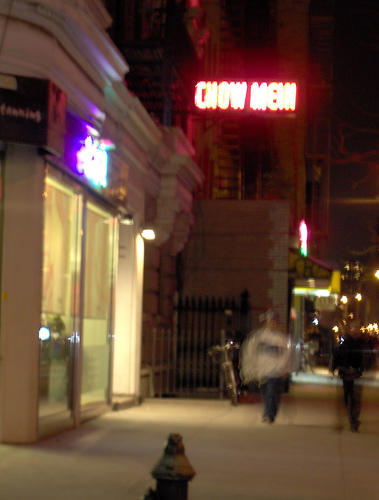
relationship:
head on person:
[256, 307, 286, 327] [236, 304, 304, 426]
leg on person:
[260, 376, 284, 426] [239, 306, 294, 427]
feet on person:
[259, 413, 276, 422] [239, 306, 294, 427]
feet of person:
[347, 415, 361, 435] [318, 320, 374, 435]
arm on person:
[244, 330, 267, 353] [241, 308, 314, 428]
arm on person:
[234, 335, 254, 390] [233, 301, 301, 430]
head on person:
[330, 322, 364, 351] [298, 307, 359, 408]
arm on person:
[327, 342, 339, 377] [328, 324, 374, 431]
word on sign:
[188, 80, 245, 114] [194, 78, 294, 112]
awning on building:
[290, 245, 338, 279] [171, 47, 310, 398]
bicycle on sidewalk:
[207, 340, 240, 406] [216, 330, 247, 401]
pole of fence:
[158, 330, 165, 398] [147, 325, 231, 395]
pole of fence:
[163, 325, 172, 395] [175, 286, 250, 392]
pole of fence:
[170, 326, 179, 395] [147, 325, 231, 395]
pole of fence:
[176, 328, 185, 399] [175, 286, 250, 392]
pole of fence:
[184, 328, 190, 397] [147, 325, 231, 395]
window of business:
[42, 178, 114, 422] [0, 0, 195, 440]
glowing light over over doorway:
[113, 202, 154, 271] [106, 189, 161, 427]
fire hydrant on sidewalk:
[132, 420, 193, 495] [37, 363, 340, 490]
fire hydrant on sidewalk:
[143, 432, 196, 499] [0, 365, 376, 497]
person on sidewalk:
[239, 306, 294, 427] [0, 365, 376, 497]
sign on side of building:
[194, 78, 294, 112] [0, 17, 241, 451]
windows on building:
[37, 170, 118, 428] [0, 53, 232, 421]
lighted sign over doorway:
[75, 133, 116, 192] [40, 165, 119, 430]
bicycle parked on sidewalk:
[204, 340, 256, 406] [0, 365, 376, 497]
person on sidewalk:
[237, 306, 294, 428] [0, 357, 349, 493]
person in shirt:
[237, 306, 294, 428] [240, 312, 306, 392]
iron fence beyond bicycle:
[152, 280, 251, 391] [210, 339, 246, 402]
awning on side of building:
[288, 247, 334, 287] [3, 57, 222, 453]